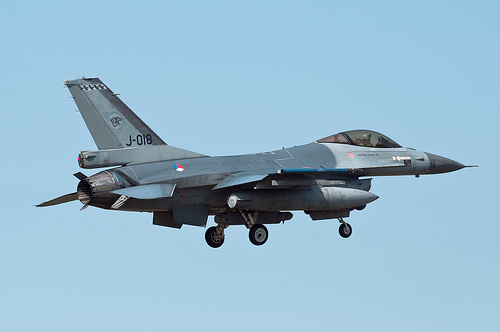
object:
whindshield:
[344, 130, 404, 149]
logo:
[175, 162, 184, 172]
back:
[33, 77, 184, 229]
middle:
[221, 145, 285, 174]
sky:
[385, 7, 470, 79]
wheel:
[335, 213, 355, 238]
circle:
[177, 167, 187, 174]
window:
[312, 122, 408, 149]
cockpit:
[319, 124, 419, 169]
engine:
[35, 160, 133, 216]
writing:
[144, 134, 159, 144]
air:
[2, 5, 75, 25]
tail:
[60, 65, 171, 158]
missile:
[226, 182, 380, 214]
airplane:
[36, 73, 477, 251]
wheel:
[248, 218, 270, 248]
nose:
[426, 150, 487, 180]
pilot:
[354, 128, 374, 150]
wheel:
[202, 219, 225, 250]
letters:
[123, 133, 136, 147]